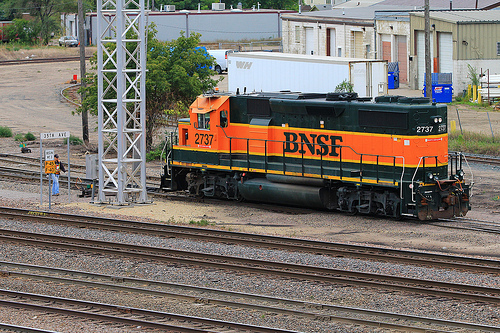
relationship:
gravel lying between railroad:
[163, 233, 245, 258] [7, 214, 495, 332]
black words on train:
[283, 127, 345, 160] [157, 87, 476, 221]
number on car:
[192, 133, 214, 145] [162, 90, 472, 221]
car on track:
[160, 87, 469, 220] [170, 210, 373, 325]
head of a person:
[47, 150, 62, 170] [43, 145, 72, 188]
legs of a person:
[36, 167, 76, 214] [32, 152, 80, 205]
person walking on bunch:
[45, 151, 68, 198] [0, 152, 496, 331]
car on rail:
[160, 87, 469, 220] [86, 184, 432, 311]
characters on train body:
[276, 120, 345, 171] [281, 119, 377, 171]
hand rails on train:
[214, 125, 446, 182] [157, 87, 476, 221]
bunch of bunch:
[62, 210, 414, 323] [0, 152, 496, 331]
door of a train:
[172, 121, 199, 159] [164, 91, 482, 228]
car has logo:
[160, 87, 469, 220] [281, 125, 343, 159]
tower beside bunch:
[92, 0, 153, 207] [0, 152, 496, 331]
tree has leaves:
[79, 39, 204, 147] [159, 57, 167, 64]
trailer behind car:
[224, 50, 389, 97] [160, 87, 469, 220]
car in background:
[162, 89, 489, 254] [32, 23, 96, 89]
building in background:
[414, 17, 499, 59] [232, 13, 494, 126]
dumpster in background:
[423, 72, 460, 105] [387, 42, 486, 145]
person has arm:
[46, 154, 64, 195] [59, 158, 71, 183]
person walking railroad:
[46, 154, 64, 195] [92, 219, 337, 304]